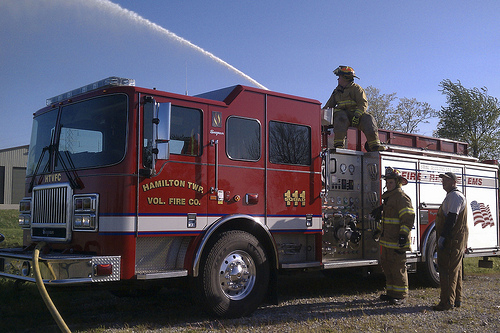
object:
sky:
[363, 29, 468, 91]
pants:
[436, 190, 468, 306]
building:
[0, 142, 32, 209]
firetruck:
[0, 76, 500, 319]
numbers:
[284, 190, 293, 206]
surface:
[0, 258, 91, 282]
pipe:
[34, 241, 72, 333]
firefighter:
[322, 65, 386, 151]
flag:
[470, 200, 495, 229]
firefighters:
[433, 173, 468, 312]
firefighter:
[371, 170, 414, 305]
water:
[79, 1, 265, 89]